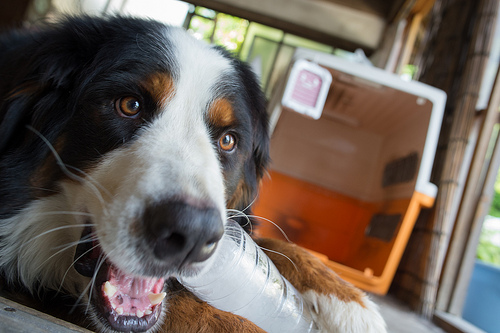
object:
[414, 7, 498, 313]
curtain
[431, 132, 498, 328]
window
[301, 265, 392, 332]
paw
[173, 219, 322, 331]
bottle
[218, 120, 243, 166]
eye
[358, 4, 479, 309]
wall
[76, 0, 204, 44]
building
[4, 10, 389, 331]
dog